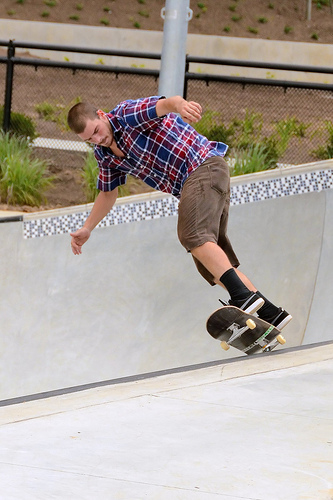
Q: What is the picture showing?
A: It is showing a swimming pool.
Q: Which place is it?
A: It is a swimming pool.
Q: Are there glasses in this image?
A: No, there are no glasses.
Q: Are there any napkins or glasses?
A: No, there are no glasses or napkins.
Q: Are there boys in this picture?
A: No, there are no boys.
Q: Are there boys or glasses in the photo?
A: No, there are no boys or glasses.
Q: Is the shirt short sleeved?
A: Yes, the shirt is short sleeved.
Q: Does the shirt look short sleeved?
A: Yes, the shirt is short sleeved.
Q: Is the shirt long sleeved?
A: No, the shirt is short sleeved.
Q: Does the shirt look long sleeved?
A: No, the shirt is short sleeved.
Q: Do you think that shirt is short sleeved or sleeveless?
A: The shirt is short sleeved.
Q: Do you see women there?
A: No, there are no women.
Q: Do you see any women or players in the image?
A: No, there are no women or players.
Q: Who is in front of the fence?
A: The man is in front of the fence.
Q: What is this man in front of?
A: The man is in front of the fence.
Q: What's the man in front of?
A: The man is in front of the fence.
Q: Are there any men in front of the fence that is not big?
A: Yes, there is a man in front of the fence.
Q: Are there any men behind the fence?
A: No, the man is in front of the fence.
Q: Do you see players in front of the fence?
A: No, there is a man in front of the fence.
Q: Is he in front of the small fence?
A: Yes, the man is in front of the fence.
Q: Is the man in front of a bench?
A: No, the man is in front of the fence.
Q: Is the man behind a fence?
A: No, the man is in front of a fence.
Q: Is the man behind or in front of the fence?
A: The man is in front of the fence.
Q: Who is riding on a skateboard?
A: The man is riding on a skateboard.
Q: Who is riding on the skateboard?
A: The man is riding on a skateboard.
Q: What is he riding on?
A: The man is riding on a skateboard.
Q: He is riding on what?
A: The man is riding on a skateboard.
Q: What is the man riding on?
A: The man is riding on a skateboard.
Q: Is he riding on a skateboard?
A: Yes, the man is riding on a skateboard.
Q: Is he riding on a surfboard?
A: No, the man is riding on a skateboard.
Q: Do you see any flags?
A: No, there are no flags.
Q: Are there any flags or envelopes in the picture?
A: No, there are no flags or envelopes.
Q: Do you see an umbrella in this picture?
A: No, there are no umbrellas.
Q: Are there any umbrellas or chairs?
A: No, there are no umbrellas or chairs.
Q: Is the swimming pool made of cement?
A: Yes, the swimming pool is made of cement.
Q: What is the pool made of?
A: The pool is made of cement.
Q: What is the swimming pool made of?
A: The pool is made of concrete.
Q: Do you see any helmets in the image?
A: No, there are no helmets.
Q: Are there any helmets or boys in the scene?
A: No, there are no helmets or boys.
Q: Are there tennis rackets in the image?
A: No, there are no tennis rackets.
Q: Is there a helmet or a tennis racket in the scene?
A: No, there are no rackets or helmets.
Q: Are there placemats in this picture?
A: No, there are no placemats.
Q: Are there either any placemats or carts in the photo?
A: No, there are no placemats or carts.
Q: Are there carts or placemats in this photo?
A: No, there are no placemats or carts.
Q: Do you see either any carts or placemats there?
A: No, there are no placemats or carts.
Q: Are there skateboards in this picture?
A: Yes, there is a skateboard.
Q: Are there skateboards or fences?
A: Yes, there is a skateboard.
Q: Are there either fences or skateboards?
A: Yes, there is a skateboard.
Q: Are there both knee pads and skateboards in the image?
A: No, there is a skateboard but no knee pads.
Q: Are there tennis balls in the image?
A: No, there are no tennis balls.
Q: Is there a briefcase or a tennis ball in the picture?
A: No, there are no tennis balls or briefcases.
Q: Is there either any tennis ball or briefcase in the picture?
A: No, there are no tennis balls or briefcases.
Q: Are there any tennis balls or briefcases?
A: No, there are no tennis balls or briefcases.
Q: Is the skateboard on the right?
A: Yes, the skateboard is on the right of the image.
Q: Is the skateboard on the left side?
A: No, the skateboard is on the right of the image.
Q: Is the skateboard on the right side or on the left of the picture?
A: The skateboard is on the right of the image.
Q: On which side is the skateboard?
A: The skateboard is on the right of the image.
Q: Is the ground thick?
A: Yes, the ground is thick.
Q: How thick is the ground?
A: The ground is thick.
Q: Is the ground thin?
A: No, the ground is thick.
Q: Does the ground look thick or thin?
A: The ground is thick.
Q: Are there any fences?
A: Yes, there is a fence.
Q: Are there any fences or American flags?
A: Yes, there is a fence.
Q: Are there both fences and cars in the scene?
A: No, there is a fence but no cars.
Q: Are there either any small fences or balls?
A: Yes, there is a small fence.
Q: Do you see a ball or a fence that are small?
A: Yes, the fence is small.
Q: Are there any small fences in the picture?
A: Yes, there is a small fence.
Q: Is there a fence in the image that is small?
A: Yes, there is a fence that is small.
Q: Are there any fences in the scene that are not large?
A: Yes, there is a small fence.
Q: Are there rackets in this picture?
A: No, there are no rackets.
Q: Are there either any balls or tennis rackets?
A: No, there are no tennis rackets or balls.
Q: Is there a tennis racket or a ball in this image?
A: No, there are no rackets or balls.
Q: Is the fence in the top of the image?
A: Yes, the fence is in the top of the image.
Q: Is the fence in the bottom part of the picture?
A: No, the fence is in the top of the image.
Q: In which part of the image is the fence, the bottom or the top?
A: The fence is in the top of the image.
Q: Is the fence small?
A: Yes, the fence is small.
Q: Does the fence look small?
A: Yes, the fence is small.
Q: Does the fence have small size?
A: Yes, the fence is small.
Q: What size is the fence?
A: The fence is small.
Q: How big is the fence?
A: The fence is small.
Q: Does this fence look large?
A: No, the fence is small.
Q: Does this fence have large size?
A: No, the fence is small.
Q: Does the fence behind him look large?
A: No, the fence is small.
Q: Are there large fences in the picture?
A: No, there is a fence but it is small.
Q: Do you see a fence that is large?
A: No, there is a fence but it is small.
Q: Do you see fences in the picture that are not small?
A: No, there is a fence but it is small.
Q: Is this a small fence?
A: Yes, this is a small fence.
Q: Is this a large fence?
A: No, this is a small fence.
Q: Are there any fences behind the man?
A: Yes, there is a fence behind the man.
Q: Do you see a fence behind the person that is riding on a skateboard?
A: Yes, there is a fence behind the man.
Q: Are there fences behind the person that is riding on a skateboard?
A: Yes, there is a fence behind the man.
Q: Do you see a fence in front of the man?
A: No, the fence is behind the man.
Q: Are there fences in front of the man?
A: No, the fence is behind the man.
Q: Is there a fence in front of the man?
A: No, the fence is behind the man.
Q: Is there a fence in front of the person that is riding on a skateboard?
A: No, the fence is behind the man.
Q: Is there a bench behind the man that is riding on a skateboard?
A: No, there is a fence behind the man.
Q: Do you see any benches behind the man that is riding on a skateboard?
A: No, there is a fence behind the man.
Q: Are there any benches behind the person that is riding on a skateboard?
A: No, there is a fence behind the man.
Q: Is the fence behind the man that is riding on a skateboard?
A: Yes, the fence is behind the man.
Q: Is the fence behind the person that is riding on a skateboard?
A: Yes, the fence is behind the man.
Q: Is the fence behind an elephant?
A: No, the fence is behind the man.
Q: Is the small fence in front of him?
A: No, the fence is behind a man.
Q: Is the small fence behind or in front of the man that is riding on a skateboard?
A: The fence is behind the man.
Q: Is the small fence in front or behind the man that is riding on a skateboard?
A: The fence is behind the man.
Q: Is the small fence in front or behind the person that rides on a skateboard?
A: The fence is behind the man.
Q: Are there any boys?
A: No, there are no boys.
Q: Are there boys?
A: No, there are no boys.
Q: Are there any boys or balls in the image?
A: No, there are no boys or balls.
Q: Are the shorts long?
A: Yes, the shorts are long.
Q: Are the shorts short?
A: No, the shorts are long.